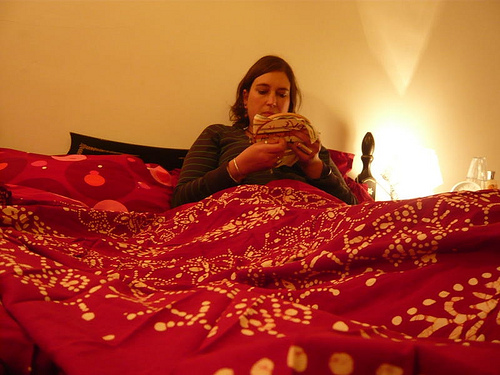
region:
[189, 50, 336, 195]
this is a lady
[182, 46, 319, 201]
the lady is on the bed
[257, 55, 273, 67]
this is the hair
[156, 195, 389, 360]
the sheet is red in color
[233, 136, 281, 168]
this is the hand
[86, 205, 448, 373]
the sheet is big in size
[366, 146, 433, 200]
the light is on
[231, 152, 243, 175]
this is a wrist band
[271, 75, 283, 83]
the lady is light skinned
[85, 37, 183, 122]
the wall is cream in color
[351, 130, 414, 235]
This is a bed pillar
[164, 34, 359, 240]
This is a woman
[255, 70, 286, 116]
Face of a woman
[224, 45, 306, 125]
Head of a woman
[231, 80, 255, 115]
Ear of a woman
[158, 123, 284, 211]
Hand of a woman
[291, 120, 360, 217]
Hand of a woman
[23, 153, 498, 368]
This is a bed cover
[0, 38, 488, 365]
This is a woman reading a book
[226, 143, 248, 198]
A wrist bangle on hand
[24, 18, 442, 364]
This is in a bedroom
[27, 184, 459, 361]
These are blankets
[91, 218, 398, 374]
The blankets are yellow and red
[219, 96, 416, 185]
The lady is sewing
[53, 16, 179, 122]
The wall is yellow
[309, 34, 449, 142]
This light is bright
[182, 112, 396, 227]
The lady is wearing a sweater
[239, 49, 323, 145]
The lady has brown hair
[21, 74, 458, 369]
The room is dim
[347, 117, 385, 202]
This bed post is wood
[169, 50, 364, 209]
A women knitting in bed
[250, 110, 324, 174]
Her hands hold the pictue and knit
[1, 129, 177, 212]
Red and black pillow by the women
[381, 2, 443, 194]
Light shining on the wall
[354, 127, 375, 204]
the rounded post for the bed frame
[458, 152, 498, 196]
Atuff sticking out over her blanket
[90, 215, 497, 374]
Yellow designs on the red bed spread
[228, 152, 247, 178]
a braclet on the womens wrist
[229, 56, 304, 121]
The wome has brown long hair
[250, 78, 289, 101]
The eyes of the women looking down at her hands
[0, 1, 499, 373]
A woman in a bed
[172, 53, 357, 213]
The woman studying an object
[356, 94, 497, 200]
Te lighted corner of the bed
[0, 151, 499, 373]
Red spotted bed cover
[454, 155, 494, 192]
The glassware on the bedside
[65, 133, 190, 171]
A partially hidden bed pillow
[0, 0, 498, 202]
The creamy painted walls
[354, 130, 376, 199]
The brown leg of bed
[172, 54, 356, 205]
A woman in a stripped sweater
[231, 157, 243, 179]
A shiny metallic bangle